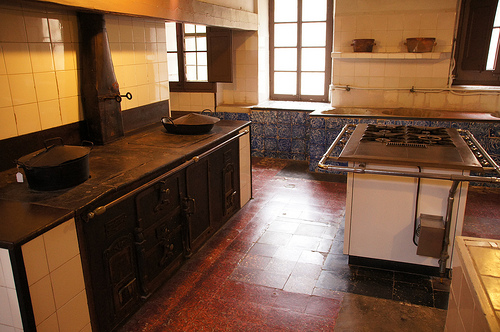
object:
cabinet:
[206, 135, 243, 229]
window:
[486, 26, 500, 71]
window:
[195, 35, 206, 52]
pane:
[270, 70, 299, 97]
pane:
[180, 22, 197, 33]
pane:
[480, 27, 500, 72]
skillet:
[160, 107, 221, 135]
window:
[299, 21, 327, 50]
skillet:
[16, 136, 99, 193]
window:
[271, 47, 300, 72]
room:
[1, 0, 500, 331]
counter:
[0, 118, 254, 250]